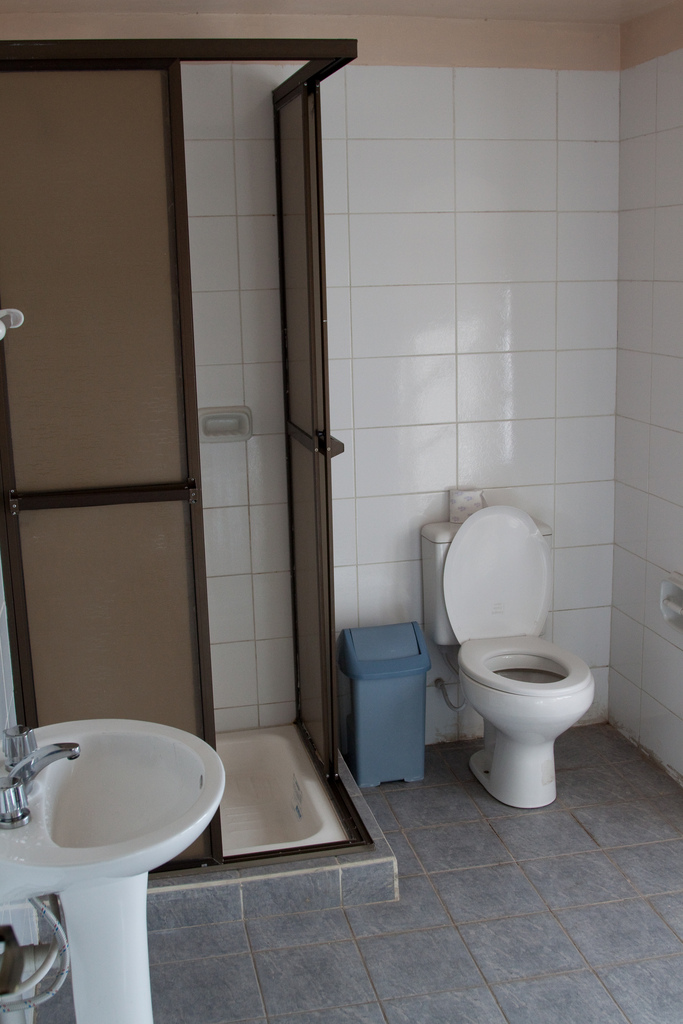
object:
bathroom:
[0, 0, 683, 1024]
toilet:
[421, 504, 595, 810]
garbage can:
[338, 621, 432, 790]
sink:
[0, 717, 227, 1023]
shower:
[0, 39, 396, 939]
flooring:
[0, 723, 679, 1022]